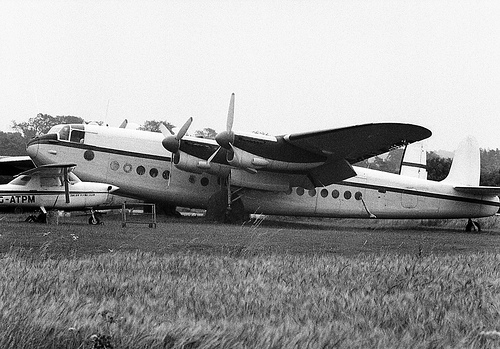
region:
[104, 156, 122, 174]
Small round circle on the side of a plane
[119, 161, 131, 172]
Small round circle on the side of a plane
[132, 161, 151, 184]
Small round circle on the side of a plane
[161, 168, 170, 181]
Small round circle on the side of a plane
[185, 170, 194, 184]
Small round circle on the side of a plane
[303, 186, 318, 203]
Small round circle on the side of a plane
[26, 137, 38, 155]
The nose of the larger plane.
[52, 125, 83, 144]
The cockpit windows of the larger plane.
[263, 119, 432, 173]
The sidewing of the larger plane.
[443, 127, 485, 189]
The tail of the larger plane.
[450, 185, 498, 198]
The tail wing of the larger plane.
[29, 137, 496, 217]
The stripe on the side of the larger plane.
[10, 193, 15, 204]
The letter A on the small plane.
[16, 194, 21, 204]
The letter T of the small plane.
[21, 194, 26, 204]
The letter P of the small plane.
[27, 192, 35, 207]
The letter M of the small plane.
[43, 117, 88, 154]
cock pit of the plane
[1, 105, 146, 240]
small plane parked next to a larger one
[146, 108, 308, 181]
2 motors on the wing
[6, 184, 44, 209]
atpm written on the small plane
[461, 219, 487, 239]
wheel down in the rear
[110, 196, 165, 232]
metal cart on the grass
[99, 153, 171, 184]
windows on side of plane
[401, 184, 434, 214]
door near rear of plane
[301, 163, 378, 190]
wing flap is pointed down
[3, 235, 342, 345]
tall grass in front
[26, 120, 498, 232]
large plane on the ground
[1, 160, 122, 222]
small plane on the ground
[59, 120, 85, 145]
cockpit of a large plane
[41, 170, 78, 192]
cockpit of a small plane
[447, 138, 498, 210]
tail of the large plane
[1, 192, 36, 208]
number on a small plane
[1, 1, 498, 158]
sky over planes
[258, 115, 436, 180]
left wing of a large plane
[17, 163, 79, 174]
wing of a small plane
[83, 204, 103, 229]
front wheel of a small plane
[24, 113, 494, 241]
Large white plane in the field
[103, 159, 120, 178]
Small round circle on a plane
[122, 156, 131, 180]
Small round circle on a plane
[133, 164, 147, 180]
Small round circle on a plane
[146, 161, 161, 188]
Small round circle on a plane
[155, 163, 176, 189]
Small round circle on a plane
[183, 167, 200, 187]
Small round circle on a plane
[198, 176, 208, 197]
Small round circle on a plane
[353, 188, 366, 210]
Small round circle on a plane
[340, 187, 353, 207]
Small round circle on a plane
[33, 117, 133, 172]
Part of an air craft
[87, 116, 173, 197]
Part of an air craft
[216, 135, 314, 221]
Part of an air craft